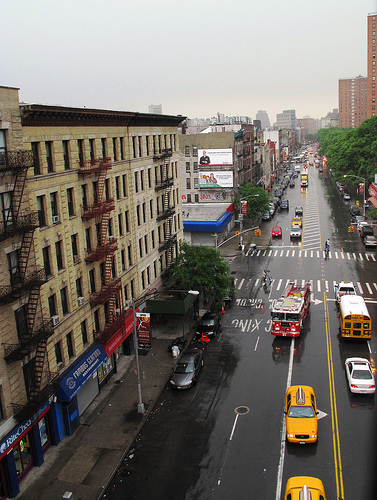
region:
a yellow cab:
[283, 384, 319, 445]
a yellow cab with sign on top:
[284, 476, 328, 499]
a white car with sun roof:
[344, 355, 374, 394]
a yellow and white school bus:
[338, 294, 373, 341]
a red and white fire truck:
[268, 278, 313, 338]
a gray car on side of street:
[169, 345, 206, 390]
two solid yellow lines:
[322, 292, 345, 498]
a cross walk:
[241, 243, 375, 263]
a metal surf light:
[132, 284, 198, 413]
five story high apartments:
[0, 115, 187, 442]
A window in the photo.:
[36, 193, 45, 226]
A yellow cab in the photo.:
[285, 387, 318, 449]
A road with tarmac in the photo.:
[244, 449, 256, 482]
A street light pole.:
[134, 372, 147, 419]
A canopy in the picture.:
[71, 356, 90, 384]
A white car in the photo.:
[348, 359, 375, 397]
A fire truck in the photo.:
[270, 295, 304, 338]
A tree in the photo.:
[190, 257, 225, 294]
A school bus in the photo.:
[337, 291, 373, 341]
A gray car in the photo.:
[170, 353, 198, 389]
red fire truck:
[270, 277, 312, 339]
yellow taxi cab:
[284, 384, 319, 448]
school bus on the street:
[330, 295, 372, 343]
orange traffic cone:
[218, 303, 226, 315]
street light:
[127, 287, 200, 412]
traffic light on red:
[211, 222, 267, 289]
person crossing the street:
[321, 237, 332, 259]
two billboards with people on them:
[195, 142, 235, 191]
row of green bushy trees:
[307, 112, 374, 165]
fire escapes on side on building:
[78, 153, 127, 330]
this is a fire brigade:
[269, 279, 310, 333]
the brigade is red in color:
[268, 280, 312, 337]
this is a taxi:
[283, 380, 323, 441]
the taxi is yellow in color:
[293, 422, 307, 430]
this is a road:
[229, 358, 280, 392]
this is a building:
[23, 171, 77, 295]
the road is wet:
[141, 419, 211, 489]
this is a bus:
[337, 290, 369, 336]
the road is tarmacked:
[225, 359, 268, 391]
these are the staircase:
[86, 171, 115, 228]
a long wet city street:
[103, 142, 374, 499]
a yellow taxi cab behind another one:
[283, 384, 317, 445]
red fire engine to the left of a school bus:
[268, 280, 310, 336]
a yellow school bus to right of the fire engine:
[337, 294, 371, 337]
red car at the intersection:
[270, 225, 282, 239]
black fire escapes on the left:
[0, 150, 56, 397]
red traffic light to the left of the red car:
[253, 228, 263, 237]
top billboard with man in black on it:
[197, 148, 233, 166]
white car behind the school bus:
[345, 356, 376, 394]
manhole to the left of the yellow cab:
[234, 404, 250, 414]